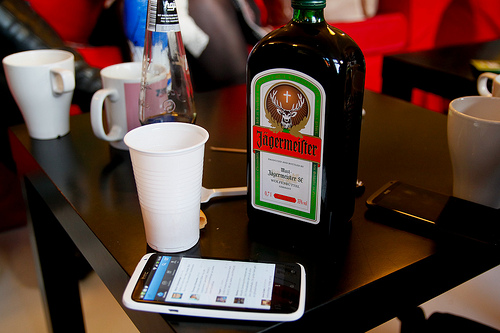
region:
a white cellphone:
[112, 248, 308, 323]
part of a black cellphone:
[361, 175, 448, 230]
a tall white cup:
[121, 118, 208, 255]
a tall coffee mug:
[2, 45, 81, 142]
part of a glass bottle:
[131, 1, 190, 122]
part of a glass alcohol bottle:
[235, 0, 369, 244]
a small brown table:
[13, 78, 498, 330]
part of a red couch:
[325, 0, 497, 109]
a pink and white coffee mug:
[90, 63, 172, 148]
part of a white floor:
[2, 225, 41, 330]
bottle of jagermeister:
[242, 0, 367, 264]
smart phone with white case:
[118, 243, 318, 322]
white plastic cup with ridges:
[113, 110, 206, 253]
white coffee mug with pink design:
[87, 56, 176, 148]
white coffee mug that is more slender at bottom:
[0, 46, 85, 143]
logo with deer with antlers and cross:
[259, 80, 313, 135]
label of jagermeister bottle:
[249, 68, 325, 227]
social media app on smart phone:
[119, 248, 314, 321]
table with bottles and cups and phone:
[5, 16, 344, 331]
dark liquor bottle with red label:
[244, 1, 369, 255]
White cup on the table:
[118, 121, 205, 247]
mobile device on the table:
[126, 246, 302, 321]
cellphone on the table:
[368, 167, 499, 242]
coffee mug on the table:
[87, 55, 179, 122]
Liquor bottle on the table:
[244, 17, 366, 235]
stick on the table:
[210, 128, 248, 166]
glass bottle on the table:
[127, 36, 208, 123]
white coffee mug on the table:
[7, 30, 74, 140]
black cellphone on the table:
[368, 172, 495, 269]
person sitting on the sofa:
[193, 6, 245, 72]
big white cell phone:
[118, 248, 313, 323]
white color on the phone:
[171, 266, 256, 297]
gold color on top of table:
[352, 228, 396, 260]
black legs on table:
[21, 232, 98, 302]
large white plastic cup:
[110, 124, 219, 251]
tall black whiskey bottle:
[243, 22, 368, 260]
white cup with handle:
[3, 50, 82, 140]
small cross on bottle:
[276, 84, 298, 104]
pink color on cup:
[114, 72, 160, 103]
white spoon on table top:
[211, 171, 236, 206]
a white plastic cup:
[125, 118, 206, 251]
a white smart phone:
[122, 250, 308, 323]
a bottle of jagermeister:
[247, 0, 355, 231]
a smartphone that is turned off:
[364, 177, 499, 256]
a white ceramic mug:
[3, 47, 76, 137]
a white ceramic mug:
[90, 60, 170, 148]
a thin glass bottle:
[140, 1, 194, 127]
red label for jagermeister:
[251, 125, 321, 164]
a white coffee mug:
[446, 90, 498, 211]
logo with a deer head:
[267, 87, 304, 132]